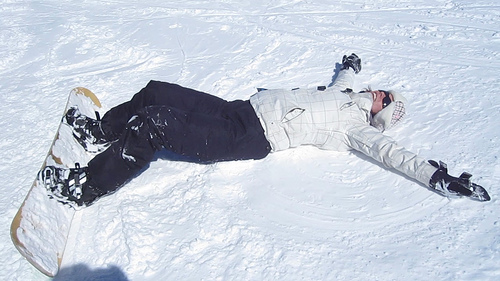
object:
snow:
[0, 0, 500, 281]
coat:
[249, 67, 443, 188]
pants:
[81, 78, 269, 202]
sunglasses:
[377, 89, 392, 109]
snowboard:
[8, 86, 104, 278]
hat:
[369, 89, 411, 134]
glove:
[427, 159, 489, 202]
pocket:
[278, 107, 305, 124]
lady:
[36, 52, 492, 212]